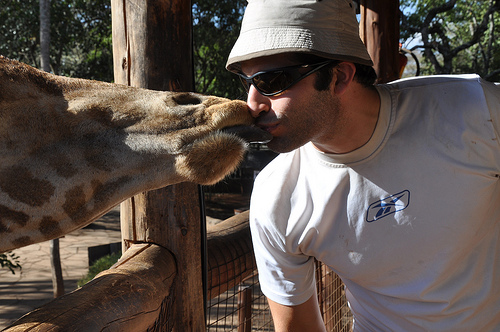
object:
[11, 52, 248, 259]
cup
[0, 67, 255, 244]
head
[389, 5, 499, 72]
tree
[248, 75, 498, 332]
shirt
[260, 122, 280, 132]
mouth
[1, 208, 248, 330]
wooden fence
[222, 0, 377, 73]
hat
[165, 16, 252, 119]
foliage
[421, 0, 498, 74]
branch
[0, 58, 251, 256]
giraffe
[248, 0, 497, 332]
man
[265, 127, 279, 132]
lips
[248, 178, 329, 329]
arm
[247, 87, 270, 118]
nose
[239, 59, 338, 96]
black glasses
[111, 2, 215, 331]
post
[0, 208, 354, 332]
fence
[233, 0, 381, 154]
head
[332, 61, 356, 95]
ear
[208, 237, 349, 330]
metal mesh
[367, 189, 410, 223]
logo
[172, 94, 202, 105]
nostril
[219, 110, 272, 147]
mouth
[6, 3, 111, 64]
foliage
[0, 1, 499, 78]
sky